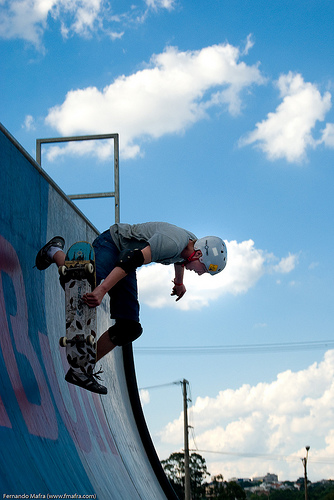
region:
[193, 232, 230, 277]
white skateboarding helmet with yellow and blue stickers on it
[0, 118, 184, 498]
blue and white wooden skateboard ramp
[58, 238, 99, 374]
blue white and black skateboard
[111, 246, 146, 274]
black elbow pad worn by skater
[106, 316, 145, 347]
black knee pad protecting knee of skater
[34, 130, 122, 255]
light gray metal handbar on skateboard ramp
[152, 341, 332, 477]
white fluffy thick clouds near horizon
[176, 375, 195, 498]
light gray metal pole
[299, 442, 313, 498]
light post near skateboard ramp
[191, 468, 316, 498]
group of houses on hillside overlooking skateboard ramp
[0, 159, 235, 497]
a skater on a ramp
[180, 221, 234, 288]
a white helmet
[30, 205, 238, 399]
skater holds a skateboard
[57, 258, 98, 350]
skateboard has white wheels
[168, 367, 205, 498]
a pole with electric wires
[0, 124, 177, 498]
a ramp for skating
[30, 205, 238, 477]
boy is going down the ramp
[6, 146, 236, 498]
skater on a slope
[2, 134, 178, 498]
slope is color blue and gray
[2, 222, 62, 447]
a red letter B on ramp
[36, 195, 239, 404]
skater coming down a halfpope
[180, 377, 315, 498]
utility poles in the background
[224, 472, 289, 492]
cityscape in the distance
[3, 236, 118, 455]
red lettering on the ramp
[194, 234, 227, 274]
gray helmet worn by skater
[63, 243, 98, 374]
bottom of the skateboard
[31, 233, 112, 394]
black and white shoes of the skater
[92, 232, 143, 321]
jean shorts worn by the skater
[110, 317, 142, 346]
black kneepad worn by the skater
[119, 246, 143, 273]
black elbowpad of the skater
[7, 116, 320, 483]
boy plays at a skateboard park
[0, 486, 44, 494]
first and last name of the photographer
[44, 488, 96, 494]
the photographer's website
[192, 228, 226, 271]
white helmet on the rider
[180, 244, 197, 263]
red strap around the helmet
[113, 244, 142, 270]
black elbow pad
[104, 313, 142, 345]
black knee pad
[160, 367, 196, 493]
telephone pole and wires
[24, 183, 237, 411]
skateboarder positions himself for his descent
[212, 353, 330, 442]
puffy white clouds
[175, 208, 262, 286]
this is a helmet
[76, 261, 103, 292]
the wheels are white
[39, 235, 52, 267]
this is a shoe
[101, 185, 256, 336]
this is a cloud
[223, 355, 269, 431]
the cloud is white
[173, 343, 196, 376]
these are some cables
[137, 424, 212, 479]
this is a tree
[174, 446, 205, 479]
the tree is old